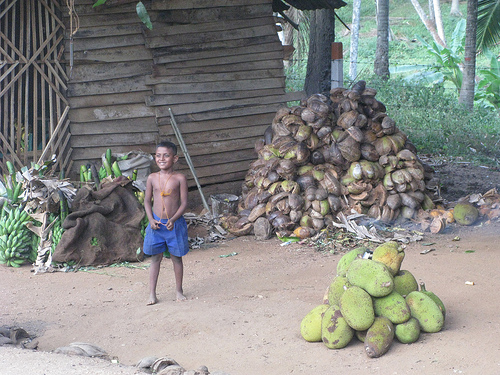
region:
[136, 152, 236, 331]
a boy is half naked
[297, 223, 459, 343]
fruits are on the ground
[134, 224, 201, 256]
the short is blue in color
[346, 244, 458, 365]
the fruits are not healthy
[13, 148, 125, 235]
the bananas are at th back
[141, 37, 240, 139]
a awoooden store is at the back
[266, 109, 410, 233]
a heap of destroyed fruits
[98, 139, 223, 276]
the boy is smilling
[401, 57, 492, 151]
plants are seen at the background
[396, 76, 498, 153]
the plants are green incolor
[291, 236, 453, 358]
a pile of melons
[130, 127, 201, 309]
the boy is in blue shorts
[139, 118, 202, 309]
the boy is bare chested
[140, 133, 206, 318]
the boy is barefooted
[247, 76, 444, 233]
a pile of rotten melons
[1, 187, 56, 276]
a big bunch of green bananas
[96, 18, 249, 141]
a stack of wood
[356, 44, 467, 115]
a barbed wire fence encloses the area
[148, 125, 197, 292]
the boy is smiling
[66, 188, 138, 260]
a canvas tarp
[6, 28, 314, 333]
a boy in a tropical area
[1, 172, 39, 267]
a large stack of bananas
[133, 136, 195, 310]
a boy not wearing a shirt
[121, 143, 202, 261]
a boy wearing blue shorts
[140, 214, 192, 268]
a pair of blue shorts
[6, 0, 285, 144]
a tall wooden structure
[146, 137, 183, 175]
the head of a boy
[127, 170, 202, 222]
the torso of a boy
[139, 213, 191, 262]
a pair of blue shorts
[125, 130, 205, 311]
The boy in blue shorts.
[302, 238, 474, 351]
The pile of green fruit.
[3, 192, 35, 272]
A pile of green bananas.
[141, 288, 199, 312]
The boys bare feet.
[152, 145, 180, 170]
The boys head.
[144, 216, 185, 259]
The blue shorts.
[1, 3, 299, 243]
The wooden building structure.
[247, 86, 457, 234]
The large pile of fruit scraps.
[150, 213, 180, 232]
The boys hands.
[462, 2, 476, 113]
trunk of the tree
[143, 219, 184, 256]
boy wearing blue color shorts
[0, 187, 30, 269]
bunch of banana kept on ground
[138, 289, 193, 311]
boy standing on mud ground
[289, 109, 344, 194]
dry coconut shell piled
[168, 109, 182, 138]
sticks resting on wall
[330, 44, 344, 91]
pole with orange and white color